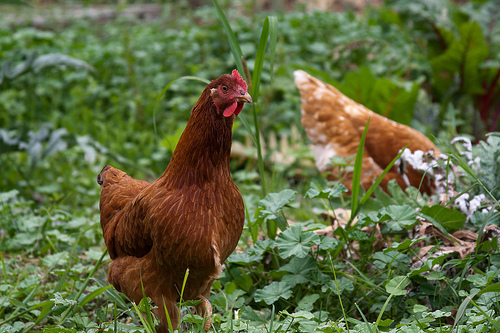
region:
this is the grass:
[23, 47, 130, 114]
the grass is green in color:
[152, 28, 219, 66]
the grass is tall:
[152, 35, 194, 62]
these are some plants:
[258, 190, 412, 330]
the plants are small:
[278, 172, 475, 331]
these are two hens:
[67, 73, 448, 320]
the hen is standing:
[80, 64, 296, 311]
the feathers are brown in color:
[183, 152, 228, 241]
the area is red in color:
[223, 104, 238, 115]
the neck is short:
[176, 110, 254, 193]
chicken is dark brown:
[81, 66, 270, 331]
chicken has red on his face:
[206, 60, 258, 123]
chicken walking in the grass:
[113, 41, 266, 330]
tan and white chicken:
[293, 56, 484, 229]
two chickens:
[97, 36, 472, 317]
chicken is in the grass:
[286, 56, 481, 229]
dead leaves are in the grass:
[290, 182, 479, 282]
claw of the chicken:
[187, 287, 231, 323]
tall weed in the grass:
[219, 2, 316, 228]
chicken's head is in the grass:
[289, 48, 498, 248]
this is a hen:
[96, 63, 253, 325]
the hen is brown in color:
[167, 164, 216, 226]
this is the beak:
[240, 93, 255, 101]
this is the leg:
[191, 295, 216, 331]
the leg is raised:
[191, 293, 211, 330]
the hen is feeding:
[318, 101, 418, 191]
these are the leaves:
[294, 244, 388, 307]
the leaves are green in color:
[257, 214, 355, 324]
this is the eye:
[217, 83, 230, 93]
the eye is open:
[217, 88, 232, 92]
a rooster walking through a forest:
[79, 63, 298, 320]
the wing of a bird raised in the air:
[285, 68, 452, 216]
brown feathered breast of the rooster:
[144, 198, 231, 265]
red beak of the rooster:
[233, 86, 254, 111]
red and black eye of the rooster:
[214, 81, 233, 93]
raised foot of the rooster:
[183, 290, 227, 331]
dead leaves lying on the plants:
[318, 208, 487, 271]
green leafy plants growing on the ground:
[267, 185, 384, 308]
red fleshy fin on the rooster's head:
[231, 68, 249, 90]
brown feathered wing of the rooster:
[111, 178, 178, 231]